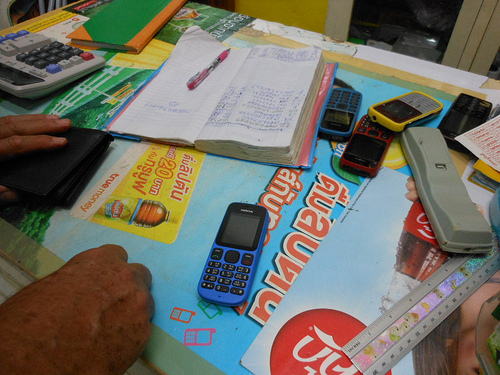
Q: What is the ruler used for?
A: Measurement.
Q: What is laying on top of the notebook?
A: Pen.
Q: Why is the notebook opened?
A: Writing in it.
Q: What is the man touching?
A: Wallet.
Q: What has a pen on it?
A: The book.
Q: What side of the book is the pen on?
A: Left.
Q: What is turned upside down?
A: The remote.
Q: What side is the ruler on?
A: Right.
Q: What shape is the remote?
A: Rectangle.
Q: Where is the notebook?
A: On the table.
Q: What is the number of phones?
A: Five.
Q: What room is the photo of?
A: Den.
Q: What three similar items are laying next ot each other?
A: Cell phones.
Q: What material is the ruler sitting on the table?
A: Plastic.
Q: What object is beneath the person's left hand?
A: A wallet.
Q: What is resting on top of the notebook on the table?
A: An ink pen.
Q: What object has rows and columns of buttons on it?
A: Cell phone.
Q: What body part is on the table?
A: A person's hand.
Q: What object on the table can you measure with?
A: A ruler.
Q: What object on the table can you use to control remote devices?
A: A remote control.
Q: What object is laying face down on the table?
A: The remote control.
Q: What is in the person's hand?
A: A wallet.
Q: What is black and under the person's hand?
A: A wallet.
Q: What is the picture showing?
A: A desk.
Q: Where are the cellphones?
A: On the desk.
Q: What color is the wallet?
A: Black.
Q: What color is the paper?
A: White.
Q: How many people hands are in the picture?
A: One.